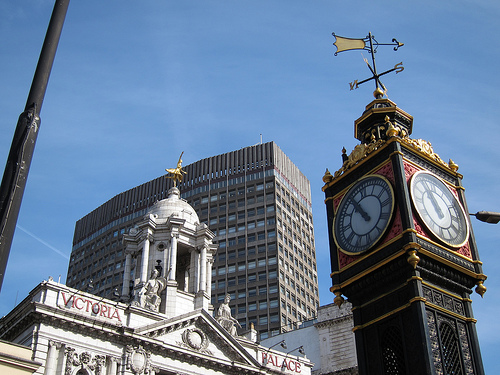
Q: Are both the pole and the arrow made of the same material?
A: Yes, both the pole and the arrow are made of metal.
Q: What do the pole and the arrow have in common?
A: The material, both the pole and the arrow are metallic.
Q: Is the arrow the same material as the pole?
A: Yes, both the arrow and the pole are made of metal.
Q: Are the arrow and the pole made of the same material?
A: Yes, both the arrow and the pole are made of metal.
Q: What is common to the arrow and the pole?
A: The material, both the arrow and the pole are metallic.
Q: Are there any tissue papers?
A: No, there are no tissue papers.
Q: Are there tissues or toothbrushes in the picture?
A: No, there are no tissues or toothbrushes.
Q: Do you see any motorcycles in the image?
A: No, there are no motorcycles.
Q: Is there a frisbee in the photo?
A: No, there are no frisbees.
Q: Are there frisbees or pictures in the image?
A: No, there are no frisbees or pictures.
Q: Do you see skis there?
A: No, there are no skis.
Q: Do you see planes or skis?
A: No, there are no skis or planes.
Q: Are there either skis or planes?
A: No, there are no skis or planes.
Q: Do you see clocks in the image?
A: Yes, there is a clock.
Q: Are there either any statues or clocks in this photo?
A: Yes, there is a clock.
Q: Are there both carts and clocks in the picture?
A: No, there is a clock but no carts.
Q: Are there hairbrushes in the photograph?
A: No, there are no hairbrushes.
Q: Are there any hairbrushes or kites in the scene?
A: No, there are no hairbrushes or kites.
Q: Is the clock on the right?
A: Yes, the clock is on the right of the image.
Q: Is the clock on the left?
A: No, the clock is on the right of the image.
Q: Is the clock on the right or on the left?
A: The clock is on the right of the image.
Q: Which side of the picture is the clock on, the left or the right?
A: The clock is on the right of the image.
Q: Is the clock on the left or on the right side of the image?
A: The clock is on the right of the image.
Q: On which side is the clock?
A: The clock is on the right of the image.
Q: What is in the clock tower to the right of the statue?
A: The clock is in the clock tower.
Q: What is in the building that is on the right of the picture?
A: The clock is in the clock tower.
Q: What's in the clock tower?
A: The clock is in the clock tower.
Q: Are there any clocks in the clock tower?
A: Yes, there is a clock in the clock tower.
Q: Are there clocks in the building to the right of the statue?
A: Yes, there is a clock in the clock tower.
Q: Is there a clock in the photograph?
A: Yes, there is a clock.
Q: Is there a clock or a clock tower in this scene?
A: Yes, there is a clock.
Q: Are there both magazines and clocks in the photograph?
A: No, there is a clock but no magazines.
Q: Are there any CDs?
A: No, there are no cds.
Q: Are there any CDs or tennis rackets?
A: No, there are no CDs or tennis rackets.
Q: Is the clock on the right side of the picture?
A: Yes, the clock is on the right of the image.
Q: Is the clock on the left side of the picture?
A: No, the clock is on the right of the image.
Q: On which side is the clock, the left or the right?
A: The clock is on the right of the image.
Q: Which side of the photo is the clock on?
A: The clock is on the right of the image.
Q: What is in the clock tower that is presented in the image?
A: The clock is in the clock tower.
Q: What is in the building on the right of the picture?
A: The clock is in the clock tower.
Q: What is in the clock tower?
A: The clock is in the clock tower.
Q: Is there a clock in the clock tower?
A: Yes, there is a clock in the clock tower.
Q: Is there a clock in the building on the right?
A: Yes, there is a clock in the clock tower.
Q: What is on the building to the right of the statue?
A: The clock is on the clock tower.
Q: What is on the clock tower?
A: The clock is on the clock tower.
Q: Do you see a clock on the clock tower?
A: Yes, there is a clock on the clock tower.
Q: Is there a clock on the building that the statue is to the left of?
A: Yes, there is a clock on the clock tower.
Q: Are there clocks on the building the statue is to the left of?
A: Yes, there is a clock on the clock tower.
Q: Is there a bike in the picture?
A: No, there are no bikes.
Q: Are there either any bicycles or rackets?
A: No, there are no bicycles or rackets.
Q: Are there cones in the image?
A: No, there are no cones.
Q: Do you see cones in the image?
A: No, there are no cones.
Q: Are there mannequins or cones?
A: No, there are no cones or mannequins.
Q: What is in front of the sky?
A: The pole is in front of the sky.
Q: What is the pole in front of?
A: The pole is in front of the sky.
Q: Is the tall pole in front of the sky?
A: Yes, the pole is in front of the sky.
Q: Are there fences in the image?
A: No, there are no fences.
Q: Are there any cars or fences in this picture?
A: No, there are no fences or cars.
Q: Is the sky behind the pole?
A: Yes, the sky is behind the pole.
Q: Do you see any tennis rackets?
A: No, there are no tennis rackets.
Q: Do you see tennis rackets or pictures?
A: No, there are no tennis rackets or pictures.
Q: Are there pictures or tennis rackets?
A: No, there are no tennis rackets or pictures.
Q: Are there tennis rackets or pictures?
A: No, there are no tennis rackets or pictures.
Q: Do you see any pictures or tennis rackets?
A: No, there are no tennis rackets or pictures.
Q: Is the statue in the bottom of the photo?
A: Yes, the statue is in the bottom of the image.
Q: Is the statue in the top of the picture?
A: No, the statue is in the bottom of the image.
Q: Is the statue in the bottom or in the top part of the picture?
A: The statue is in the bottom of the image.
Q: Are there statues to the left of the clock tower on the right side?
A: Yes, there is a statue to the left of the clock tower.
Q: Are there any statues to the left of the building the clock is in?
A: Yes, there is a statue to the left of the clock tower.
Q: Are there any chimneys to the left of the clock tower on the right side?
A: No, there is a statue to the left of the clock tower.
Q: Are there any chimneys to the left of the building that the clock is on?
A: No, there is a statue to the left of the clock tower.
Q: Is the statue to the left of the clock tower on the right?
A: Yes, the statue is to the left of the clock tower.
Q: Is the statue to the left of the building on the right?
A: Yes, the statue is to the left of the clock tower.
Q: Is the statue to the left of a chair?
A: No, the statue is to the left of the clock tower.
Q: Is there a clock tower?
A: Yes, there is a clock tower.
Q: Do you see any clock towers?
A: Yes, there is a clock tower.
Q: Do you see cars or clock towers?
A: Yes, there is a clock tower.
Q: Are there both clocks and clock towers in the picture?
A: Yes, there are both a clock tower and a clock.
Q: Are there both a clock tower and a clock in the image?
A: Yes, there are both a clock tower and a clock.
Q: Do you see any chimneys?
A: No, there are no chimneys.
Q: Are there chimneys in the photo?
A: No, there are no chimneys.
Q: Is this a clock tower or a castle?
A: This is a clock tower.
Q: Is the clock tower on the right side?
A: Yes, the clock tower is on the right of the image.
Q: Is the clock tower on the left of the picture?
A: No, the clock tower is on the right of the image.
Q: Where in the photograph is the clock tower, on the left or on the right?
A: The clock tower is on the right of the image.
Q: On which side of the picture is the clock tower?
A: The clock tower is on the right of the image.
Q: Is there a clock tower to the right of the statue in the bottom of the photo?
A: Yes, there is a clock tower to the right of the statue.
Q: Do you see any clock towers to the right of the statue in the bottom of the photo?
A: Yes, there is a clock tower to the right of the statue.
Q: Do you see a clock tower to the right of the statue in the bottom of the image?
A: Yes, there is a clock tower to the right of the statue.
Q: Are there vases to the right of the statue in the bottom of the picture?
A: No, there is a clock tower to the right of the statue.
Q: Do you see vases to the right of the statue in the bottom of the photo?
A: No, there is a clock tower to the right of the statue.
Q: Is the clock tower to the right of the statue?
A: Yes, the clock tower is to the right of the statue.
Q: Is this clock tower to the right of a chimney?
A: No, the clock tower is to the right of the statue.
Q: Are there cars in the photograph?
A: No, there are no cars.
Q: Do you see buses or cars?
A: No, there are no cars or buses.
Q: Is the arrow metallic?
A: Yes, the arrow is metallic.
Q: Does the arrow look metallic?
A: Yes, the arrow is metallic.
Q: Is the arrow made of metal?
A: Yes, the arrow is made of metal.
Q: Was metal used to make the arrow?
A: Yes, the arrow is made of metal.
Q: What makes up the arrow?
A: The arrow is made of metal.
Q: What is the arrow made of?
A: The arrow is made of metal.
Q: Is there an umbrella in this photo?
A: No, there are no umbrellas.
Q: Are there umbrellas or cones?
A: No, there are no umbrellas or cones.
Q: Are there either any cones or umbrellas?
A: No, there are no umbrellas or cones.